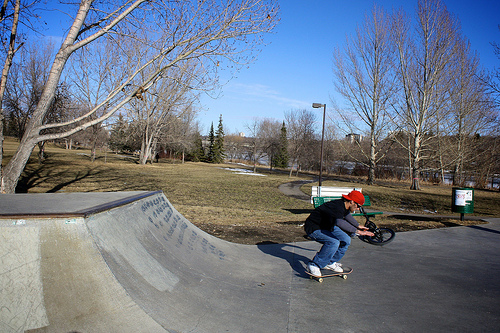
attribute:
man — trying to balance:
[294, 193, 376, 310]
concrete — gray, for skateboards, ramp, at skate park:
[183, 261, 268, 302]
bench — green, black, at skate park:
[315, 196, 323, 208]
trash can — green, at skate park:
[456, 187, 469, 219]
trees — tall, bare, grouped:
[365, 23, 483, 119]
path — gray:
[279, 179, 305, 202]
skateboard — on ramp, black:
[312, 267, 360, 276]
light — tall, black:
[311, 98, 334, 192]